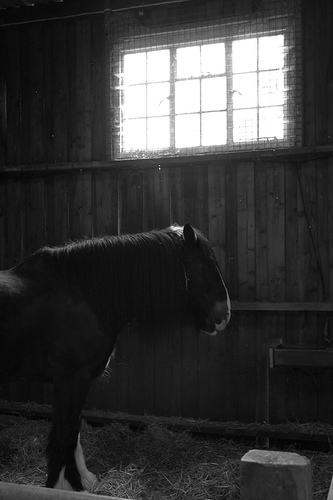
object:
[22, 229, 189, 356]
long mane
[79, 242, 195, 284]
mane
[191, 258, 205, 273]
eye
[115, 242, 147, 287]
fur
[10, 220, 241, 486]
animal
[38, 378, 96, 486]
leg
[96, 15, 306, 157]
screened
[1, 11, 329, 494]
barn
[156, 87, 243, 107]
handles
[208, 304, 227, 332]
nose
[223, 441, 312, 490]
stone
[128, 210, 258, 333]
head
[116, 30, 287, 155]
windows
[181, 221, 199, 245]
ear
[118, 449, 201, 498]
grass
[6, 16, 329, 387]
photo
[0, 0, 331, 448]
wall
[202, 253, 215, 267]
eye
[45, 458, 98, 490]
feet